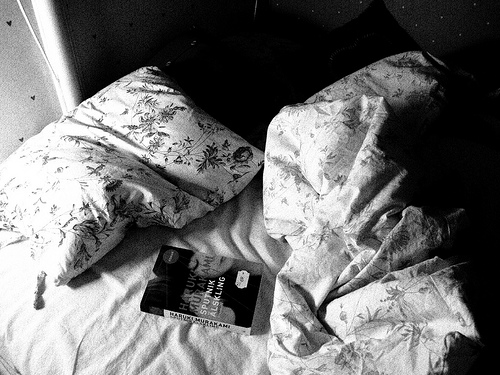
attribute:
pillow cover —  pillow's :
[0, 65, 263, 286]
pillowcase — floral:
[2, 55, 262, 274]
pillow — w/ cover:
[42, 126, 204, 210]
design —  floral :
[125, 93, 184, 156]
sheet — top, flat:
[259, 30, 499, 372]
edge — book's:
[186, 251, 238, 326]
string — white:
[13, 1, 67, 100]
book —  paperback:
[138, 240, 268, 342]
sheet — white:
[0, 194, 288, 374]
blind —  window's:
[0, 0, 45, 155]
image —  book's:
[147, 249, 268, 329]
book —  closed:
[121, 235, 318, 355]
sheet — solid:
[8, 306, 161, 372]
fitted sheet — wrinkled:
[2, 186, 292, 373]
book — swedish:
[133, 239, 268, 352]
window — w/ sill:
[40, 0, 495, 205]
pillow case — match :
[1, 66, 266, 286]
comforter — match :
[262, 50, 484, 373]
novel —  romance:
[140, 242, 263, 335]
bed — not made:
[4, 155, 493, 374]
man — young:
[184, 285, 234, 323]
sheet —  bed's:
[42, 319, 271, 373]